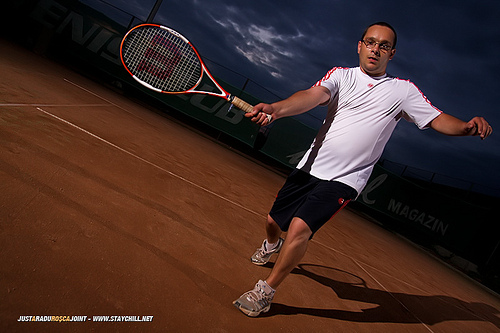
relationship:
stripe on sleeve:
[317, 61, 340, 85] [318, 64, 348, 91]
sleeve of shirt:
[318, 64, 348, 91] [297, 65, 442, 200]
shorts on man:
[262, 162, 351, 237] [229, 20, 495, 316]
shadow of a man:
[256, 260, 500, 329] [229, 20, 495, 316]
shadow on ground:
[256, 260, 500, 329] [0, 56, 498, 328]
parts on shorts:
[338, 198, 347, 208] [269, 165, 360, 246]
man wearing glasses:
[229, 20, 495, 316] [365, 39, 394, 56]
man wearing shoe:
[229, 20, 495, 316] [232, 277, 277, 318]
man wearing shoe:
[229, 20, 495, 316] [252, 236, 282, 266]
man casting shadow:
[229, 20, 495, 316] [260, 260, 481, 325]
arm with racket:
[251, 77, 355, 160] [108, 13, 248, 131]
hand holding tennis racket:
[246, 98, 275, 126] [117, 18, 274, 122]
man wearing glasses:
[229, 20, 495, 316] [360, 35, 394, 53]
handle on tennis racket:
[229, 96, 273, 125] [117, 18, 274, 122]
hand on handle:
[245, 101, 280, 127] [229, 96, 273, 125]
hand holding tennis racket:
[245, 101, 280, 127] [117, 18, 274, 122]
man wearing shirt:
[229, 20, 495, 316] [297, 65, 442, 200]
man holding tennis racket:
[98, 6, 498, 311] [115, 14, 285, 131]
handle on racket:
[229, 96, 273, 125] [115, 17, 275, 131]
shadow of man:
[275, 245, 497, 330] [229, 20, 495, 316]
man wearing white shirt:
[229, 20, 495, 316] [262, 62, 460, 199]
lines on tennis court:
[22, 99, 274, 226] [0, 46, 499, 332]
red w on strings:
[142, 30, 196, 97] [120, 21, 210, 98]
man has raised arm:
[229, 20, 495, 316] [398, 87, 498, 145]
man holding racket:
[229, 20, 495, 316] [97, 9, 277, 126]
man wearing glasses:
[229, 20, 495, 316] [360, 30, 394, 49]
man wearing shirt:
[229, 20, 495, 316] [273, 54, 453, 202]